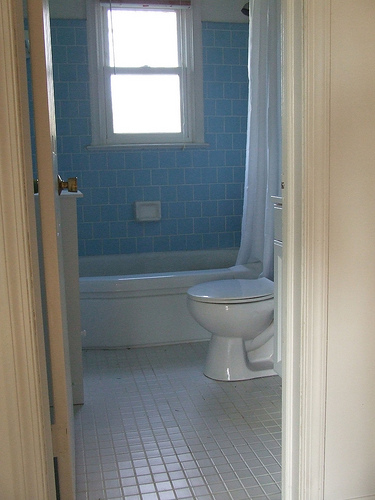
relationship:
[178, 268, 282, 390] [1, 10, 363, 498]
toilet in bathroom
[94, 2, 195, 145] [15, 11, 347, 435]
window in bathroom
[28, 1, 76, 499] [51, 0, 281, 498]
door in bathroom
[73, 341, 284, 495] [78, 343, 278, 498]
floor has tiles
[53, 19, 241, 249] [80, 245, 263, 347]
blue tiles in bathtub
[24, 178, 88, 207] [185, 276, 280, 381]
counter front toilet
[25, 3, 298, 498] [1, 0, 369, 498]
bathroom in picture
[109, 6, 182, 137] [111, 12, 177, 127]
picture taken day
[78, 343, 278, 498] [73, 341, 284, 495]
tiles on floor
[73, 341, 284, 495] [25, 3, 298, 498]
floor in bathroom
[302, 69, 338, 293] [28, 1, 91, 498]
moulding around door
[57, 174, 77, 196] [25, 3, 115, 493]
door knob on door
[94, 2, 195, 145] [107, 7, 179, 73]
window with blinds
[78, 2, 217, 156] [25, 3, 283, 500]
window in bathroom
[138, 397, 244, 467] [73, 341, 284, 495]
squares on floor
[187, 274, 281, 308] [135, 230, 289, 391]
lid on toilet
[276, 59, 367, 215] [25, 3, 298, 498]
wall outside bathroom